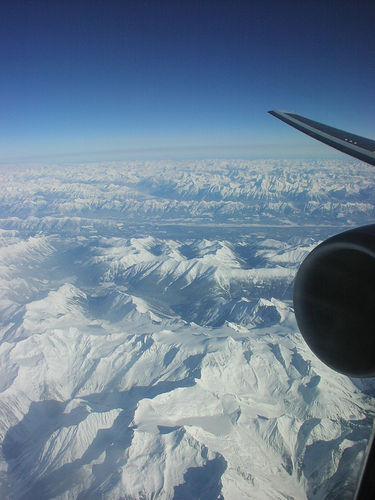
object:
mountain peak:
[171, 421, 203, 448]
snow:
[167, 426, 250, 500]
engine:
[292, 222, 373, 378]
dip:
[125, 276, 164, 303]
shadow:
[302, 412, 372, 500]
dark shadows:
[22, 402, 139, 500]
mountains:
[0, 224, 58, 291]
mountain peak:
[158, 424, 230, 498]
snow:
[1, 155, 375, 500]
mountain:
[0, 155, 375, 500]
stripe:
[267, 109, 375, 166]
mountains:
[251, 197, 301, 217]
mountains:
[0, 175, 55, 222]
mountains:
[178, 237, 240, 328]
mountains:
[0, 215, 122, 233]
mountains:
[325, 181, 375, 206]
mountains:
[180, 320, 290, 387]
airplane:
[265, 109, 375, 497]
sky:
[0, 5, 375, 177]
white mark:
[354, 141, 357, 145]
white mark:
[348, 139, 353, 143]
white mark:
[345, 138, 349, 142]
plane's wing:
[267, 105, 375, 170]